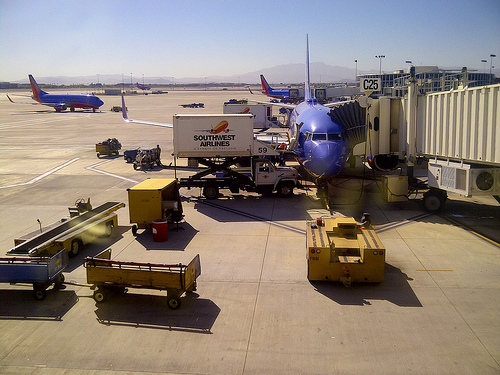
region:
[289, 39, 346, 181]
blue airplane standing still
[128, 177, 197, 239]
luggage rack on tarp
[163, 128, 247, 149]
name of airline printed on truck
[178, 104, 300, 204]
truck next to aircraft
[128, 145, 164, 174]
person standing in back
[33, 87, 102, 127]
second blue plane coming in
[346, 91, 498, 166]
walkway for passengers to board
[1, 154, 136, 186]
lines on the ground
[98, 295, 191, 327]
shadow from the truck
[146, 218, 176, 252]
waste container near truck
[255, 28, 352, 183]
Airplane connected to a jet bridge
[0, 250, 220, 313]
An empty baggage trolley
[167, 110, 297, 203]
A truck advertising Southwest Airlines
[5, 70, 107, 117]
A blue and red airplane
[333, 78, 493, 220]
Jet bridge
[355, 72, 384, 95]
A sign for gate C25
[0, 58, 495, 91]
Hazy mountains in the distance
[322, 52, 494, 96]
Airport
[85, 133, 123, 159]
Small motorized cart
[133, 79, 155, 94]
Blue and red airplane in the distance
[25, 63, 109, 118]
blue and red plane in distance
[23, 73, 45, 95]
red and blue plane fiin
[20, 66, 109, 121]
southwest airlines plane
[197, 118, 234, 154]
logo on side of truck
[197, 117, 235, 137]
image of red and orange plane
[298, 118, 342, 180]
cockpit of a large plane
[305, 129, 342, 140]
front windows of plane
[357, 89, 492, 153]
metal walkway to plane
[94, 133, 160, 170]
baggage cars on tarmac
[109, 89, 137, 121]
tip of side wing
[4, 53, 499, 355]
an airport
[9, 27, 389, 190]
planes on the tarmac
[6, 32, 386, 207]
a Southwest airlines area of the airport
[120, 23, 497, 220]
a plane at the gate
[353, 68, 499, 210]
gate number 25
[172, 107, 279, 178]
a white truck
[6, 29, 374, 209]
the planes are blue and red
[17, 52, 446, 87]
hills are seen in the background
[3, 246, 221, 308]
carts for carrying luggage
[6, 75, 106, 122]
one plane waiting on the tarmac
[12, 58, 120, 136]
Blue and red airplane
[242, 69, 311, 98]
Blue and red airplane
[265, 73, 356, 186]
Blue and red airplane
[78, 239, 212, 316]
Small cart on the pavement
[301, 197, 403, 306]
Small cart on the pavement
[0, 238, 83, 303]
Small cart on the pavement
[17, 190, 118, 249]
Small cart on the pavement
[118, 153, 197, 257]
Small cart on the pavement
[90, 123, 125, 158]
Small cart on the pavement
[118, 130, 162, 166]
Small cart on the pavement